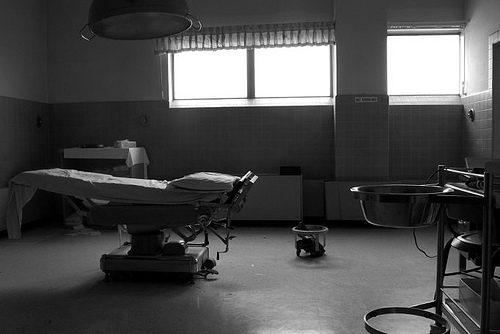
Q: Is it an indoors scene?
A: Yes, it is indoors.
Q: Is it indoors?
A: Yes, it is indoors.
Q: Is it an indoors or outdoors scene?
A: It is indoors.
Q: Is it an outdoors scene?
A: No, it is indoors.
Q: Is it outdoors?
A: No, it is indoors.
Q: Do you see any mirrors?
A: No, there are no mirrors.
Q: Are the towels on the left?
A: Yes, the towels are on the left of the image.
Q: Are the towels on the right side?
A: No, the towels are on the left of the image.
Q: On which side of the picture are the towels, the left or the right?
A: The towels are on the left of the image.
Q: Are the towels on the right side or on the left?
A: The towels are on the left of the image.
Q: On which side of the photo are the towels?
A: The towels are on the left of the image.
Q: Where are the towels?
A: The towels are on the floor.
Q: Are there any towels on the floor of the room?
A: Yes, there are towels on the floor.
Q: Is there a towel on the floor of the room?
A: Yes, there are towels on the floor.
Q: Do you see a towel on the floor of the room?
A: Yes, there are towels on the floor.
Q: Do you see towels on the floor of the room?
A: Yes, there are towels on the floor.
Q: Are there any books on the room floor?
A: No, there are towels on the floor.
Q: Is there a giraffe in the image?
A: No, there are no giraffes.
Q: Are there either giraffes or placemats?
A: No, there are no giraffes or placemats.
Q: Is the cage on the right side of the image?
A: Yes, the cage is on the right of the image.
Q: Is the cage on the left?
A: No, the cage is on the right of the image.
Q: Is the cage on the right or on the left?
A: The cage is on the right of the image.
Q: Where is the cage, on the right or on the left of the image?
A: The cage is on the right of the image.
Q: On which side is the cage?
A: The cage is on the right of the image.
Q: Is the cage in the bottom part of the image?
A: Yes, the cage is in the bottom of the image.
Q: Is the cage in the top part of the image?
A: No, the cage is in the bottom of the image.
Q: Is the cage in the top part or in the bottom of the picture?
A: The cage is in the bottom of the image.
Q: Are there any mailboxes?
A: No, there are no mailboxes.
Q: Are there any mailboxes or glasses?
A: No, there are no mailboxes or glasses.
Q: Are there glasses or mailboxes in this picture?
A: No, there are no mailboxes or glasses.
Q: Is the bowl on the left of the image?
A: Yes, the bowl is on the left of the image.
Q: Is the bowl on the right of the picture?
A: No, the bowl is on the left of the image.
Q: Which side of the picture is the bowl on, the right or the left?
A: The bowl is on the left of the image.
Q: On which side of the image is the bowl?
A: The bowl is on the left of the image.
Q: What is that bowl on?
A: The bowl is on the table.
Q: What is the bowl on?
A: The bowl is on the table.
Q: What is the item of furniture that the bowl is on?
A: The piece of furniture is a table.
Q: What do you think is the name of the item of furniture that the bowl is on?
A: The piece of furniture is a table.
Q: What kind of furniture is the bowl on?
A: The bowl is on the table.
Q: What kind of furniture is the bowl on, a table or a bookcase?
A: The bowl is on a table.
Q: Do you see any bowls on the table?
A: Yes, there is a bowl on the table.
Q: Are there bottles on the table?
A: No, there is a bowl on the table.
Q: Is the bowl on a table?
A: Yes, the bowl is on a table.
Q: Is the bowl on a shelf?
A: No, the bowl is on a table.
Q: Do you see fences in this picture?
A: No, there are no fences.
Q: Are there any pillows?
A: Yes, there is a pillow.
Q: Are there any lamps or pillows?
A: Yes, there is a pillow.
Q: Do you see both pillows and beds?
A: Yes, there are both a pillow and a bed.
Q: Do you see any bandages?
A: No, there are no bandages.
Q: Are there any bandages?
A: No, there are no bandages.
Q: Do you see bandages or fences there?
A: No, there are no bandages or fences.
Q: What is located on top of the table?
A: The pillow is on top of the table.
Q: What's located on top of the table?
A: The pillow is on top of the table.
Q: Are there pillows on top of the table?
A: Yes, there is a pillow on top of the table.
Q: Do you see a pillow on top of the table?
A: Yes, there is a pillow on top of the table.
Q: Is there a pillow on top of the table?
A: Yes, there is a pillow on top of the table.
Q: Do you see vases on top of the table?
A: No, there is a pillow on top of the table.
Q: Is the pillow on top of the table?
A: Yes, the pillow is on top of the table.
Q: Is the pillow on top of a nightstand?
A: No, the pillow is on top of the table.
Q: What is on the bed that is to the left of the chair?
A: The pillow is on the bed.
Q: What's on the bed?
A: The pillow is on the bed.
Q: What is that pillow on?
A: The pillow is on the bed.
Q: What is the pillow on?
A: The pillow is on the bed.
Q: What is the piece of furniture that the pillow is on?
A: The piece of furniture is a bed.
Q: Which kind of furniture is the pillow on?
A: The pillow is on the bed.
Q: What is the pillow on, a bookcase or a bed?
A: The pillow is on a bed.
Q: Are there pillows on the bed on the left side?
A: Yes, there is a pillow on the bed.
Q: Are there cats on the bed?
A: No, there is a pillow on the bed.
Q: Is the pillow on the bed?
A: Yes, the pillow is on the bed.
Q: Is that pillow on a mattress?
A: No, the pillow is on the bed.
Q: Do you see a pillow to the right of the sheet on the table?
A: Yes, there is a pillow to the right of the bed sheet.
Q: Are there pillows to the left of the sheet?
A: No, the pillow is to the right of the sheet.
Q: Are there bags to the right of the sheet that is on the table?
A: No, there is a pillow to the right of the sheet.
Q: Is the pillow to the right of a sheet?
A: Yes, the pillow is to the right of a sheet.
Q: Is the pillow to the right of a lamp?
A: No, the pillow is to the right of a sheet.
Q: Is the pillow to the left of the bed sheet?
A: No, the pillow is to the right of the bed sheet.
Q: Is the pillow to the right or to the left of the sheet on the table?
A: The pillow is to the right of the bed sheet.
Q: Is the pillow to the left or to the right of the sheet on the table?
A: The pillow is to the right of the bed sheet.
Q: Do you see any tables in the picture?
A: Yes, there is a table.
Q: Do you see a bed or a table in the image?
A: Yes, there is a table.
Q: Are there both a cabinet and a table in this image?
A: Yes, there are both a table and a cabinet.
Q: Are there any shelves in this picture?
A: No, there are no shelves.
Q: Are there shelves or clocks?
A: No, there are no shelves or clocks.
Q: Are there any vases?
A: No, there are no vases.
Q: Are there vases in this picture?
A: No, there are no vases.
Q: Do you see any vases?
A: No, there are no vases.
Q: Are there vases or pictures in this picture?
A: No, there are no vases or pictures.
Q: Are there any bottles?
A: No, there are no bottles.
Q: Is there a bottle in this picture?
A: No, there are no bottles.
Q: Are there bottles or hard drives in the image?
A: No, there are no bottles or hard drives.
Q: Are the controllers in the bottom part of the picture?
A: Yes, the controllers are in the bottom of the image.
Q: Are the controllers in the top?
A: No, the controllers are in the bottom of the image.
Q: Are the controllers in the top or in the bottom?
A: The controllers are in the bottom of the image.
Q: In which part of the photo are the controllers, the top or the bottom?
A: The controllers are in the bottom of the image.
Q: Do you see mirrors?
A: No, there are no mirrors.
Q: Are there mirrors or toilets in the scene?
A: No, there are no mirrors or toilets.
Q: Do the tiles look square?
A: Yes, the tiles are square.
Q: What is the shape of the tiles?
A: The tiles are square.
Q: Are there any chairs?
A: Yes, there is a chair.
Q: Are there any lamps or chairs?
A: Yes, there is a chair.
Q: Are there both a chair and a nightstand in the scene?
A: No, there is a chair but no nightstands.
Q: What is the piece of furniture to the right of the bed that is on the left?
A: The piece of furniture is a chair.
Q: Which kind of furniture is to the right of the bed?
A: The piece of furniture is a chair.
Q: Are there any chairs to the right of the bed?
A: Yes, there is a chair to the right of the bed.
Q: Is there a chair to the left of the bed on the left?
A: No, the chair is to the right of the bed.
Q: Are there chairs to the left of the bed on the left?
A: No, the chair is to the right of the bed.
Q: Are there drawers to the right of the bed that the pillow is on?
A: No, there is a chair to the right of the bed.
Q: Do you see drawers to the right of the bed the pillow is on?
A: No, there is a chair to the right of the bed.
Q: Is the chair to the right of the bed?
A: Yes, the chair is to the right of the bed.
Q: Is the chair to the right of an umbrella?
A: No, the chair is to the right of the bed.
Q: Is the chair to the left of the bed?
A: No, the chair is to the right of the bed.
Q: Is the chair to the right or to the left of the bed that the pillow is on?
A: The chair is to the right of the bed.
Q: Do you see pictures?
A: No, there are no pictures.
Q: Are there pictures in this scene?
A: No, there are no pictures.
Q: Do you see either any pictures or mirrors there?
A: No, there are no pictures or mirrors.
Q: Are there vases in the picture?
A: No, there are no vases.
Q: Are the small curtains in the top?
A: Yes, the curtains are in the top of the image.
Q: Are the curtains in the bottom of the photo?
A: No, the curtains are in the top of the image.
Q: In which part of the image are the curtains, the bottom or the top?
A: The curtains are in the top of the image.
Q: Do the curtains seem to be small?
A: Yes, the curtains are small.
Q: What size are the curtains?
A: The curtains are small.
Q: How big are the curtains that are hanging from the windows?
A: The curtains are small.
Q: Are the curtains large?
A: No, the curtains are small.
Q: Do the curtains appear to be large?
A: No, the curtains are small.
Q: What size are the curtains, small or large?
A: The curtains are small.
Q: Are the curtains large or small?
A: The curtains are small.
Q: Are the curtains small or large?
A: The curtains are small.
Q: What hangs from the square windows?
A: The curtains hang from the windows.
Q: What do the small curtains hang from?
A: The curtains hang from the windows.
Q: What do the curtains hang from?
A: The curtains hang from the windows.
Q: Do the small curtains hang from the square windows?
A: Yes, the curtains hang from the windows.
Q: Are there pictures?
A: No, there are no pictures.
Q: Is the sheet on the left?
A: Yes, the sheet is on the left of the image.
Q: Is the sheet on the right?
A: No, the sheet is on the left of the image.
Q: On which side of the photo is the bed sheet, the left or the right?
A: The bed sheet is on the left of the image.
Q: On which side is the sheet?
A: The sheet is on the left of the image.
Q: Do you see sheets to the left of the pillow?
A: Yes, there is a sheet to the left of the pillow.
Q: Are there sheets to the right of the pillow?
A: No, the sheet is to the left of the pillow.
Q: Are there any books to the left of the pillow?
A: No, there is a sheet to the left of the pillow.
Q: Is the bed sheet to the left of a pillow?
A: Yes, the bed sheet is to the left of a pillow.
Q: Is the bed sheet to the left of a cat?
A: No, the bed sheet is to the left of a pillow.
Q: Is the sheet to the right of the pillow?
A: No, the sheet is to the left of the pillow.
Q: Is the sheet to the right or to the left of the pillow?
A: The sheet is to the left of the pillow.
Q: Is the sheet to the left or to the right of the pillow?
A: The sheet is to the left of the pillow.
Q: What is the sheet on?
A: The sheet is on the table.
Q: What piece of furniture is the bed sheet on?
A: The bed sheet is on the table.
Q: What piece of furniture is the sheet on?
A: The bed sheet is on the table.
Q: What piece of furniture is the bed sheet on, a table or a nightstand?
A: The bed sheet is on a table.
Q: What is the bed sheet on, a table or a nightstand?
A: The bed sheet is on a table.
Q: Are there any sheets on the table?
A: Yes, there is a sheet on the table.